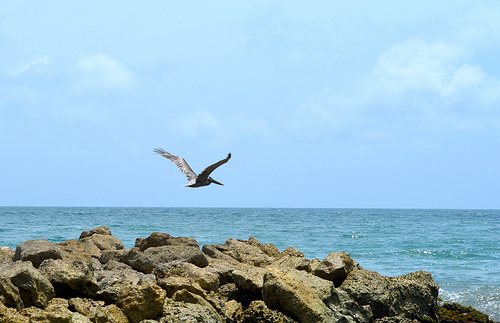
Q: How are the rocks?
A: Jagged.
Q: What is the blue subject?
A: Sky.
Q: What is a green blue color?
A: Water.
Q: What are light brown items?
A: Rocks.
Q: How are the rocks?
A: Dry.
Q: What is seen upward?
A: Sky.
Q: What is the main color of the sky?
A: Blue.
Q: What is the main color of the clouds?
A: White.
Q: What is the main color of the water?
A: Blue.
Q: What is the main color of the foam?
A: White.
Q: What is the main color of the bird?
A: Brown.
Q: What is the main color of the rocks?
A: Brown.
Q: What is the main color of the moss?
A: Green.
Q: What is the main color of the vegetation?
A: Green.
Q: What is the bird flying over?
A: Rocks.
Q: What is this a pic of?
A: A flying bird.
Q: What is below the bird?
A: Rocks.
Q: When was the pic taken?
A: During the daytime.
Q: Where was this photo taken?
A: At the beach.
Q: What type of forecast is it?
A: Clear and calm.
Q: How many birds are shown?
A: 1.